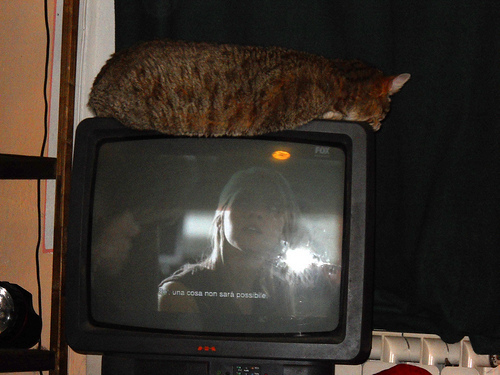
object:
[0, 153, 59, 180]
shelf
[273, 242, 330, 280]
camera flash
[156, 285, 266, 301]
subtitles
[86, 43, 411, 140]
cat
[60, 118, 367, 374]
television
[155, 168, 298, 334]
woman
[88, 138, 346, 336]
screen